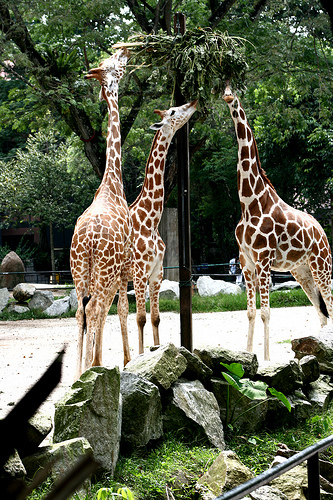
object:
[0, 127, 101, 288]
tree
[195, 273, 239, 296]
rock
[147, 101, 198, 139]
head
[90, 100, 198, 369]
giraffe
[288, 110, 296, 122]
tree leaves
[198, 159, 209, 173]
tree leaves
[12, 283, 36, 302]
rocks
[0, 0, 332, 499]
background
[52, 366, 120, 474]
rocks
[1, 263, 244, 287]
fence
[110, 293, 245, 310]
grass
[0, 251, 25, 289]
rocks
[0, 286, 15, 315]
rocks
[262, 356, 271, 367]
feet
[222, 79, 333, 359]
giraffe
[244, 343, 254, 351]
feet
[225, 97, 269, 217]
neck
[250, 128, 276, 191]
mane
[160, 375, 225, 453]
rock